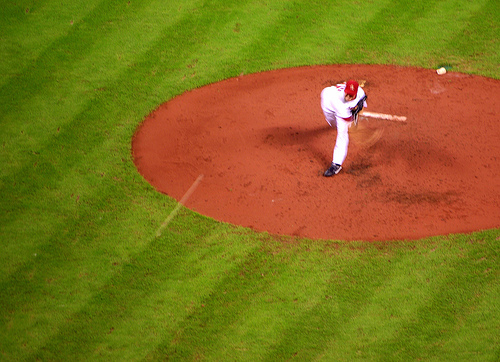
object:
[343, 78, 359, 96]
hat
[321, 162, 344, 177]
shoe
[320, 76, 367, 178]
person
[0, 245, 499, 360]
grass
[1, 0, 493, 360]
ground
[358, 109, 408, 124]
bat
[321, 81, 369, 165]
clothing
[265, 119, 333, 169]
shadow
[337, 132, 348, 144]
knee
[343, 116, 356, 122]
elbow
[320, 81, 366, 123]
shirt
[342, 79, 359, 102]
head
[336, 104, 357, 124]
arm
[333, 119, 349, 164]
leg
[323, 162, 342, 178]
foot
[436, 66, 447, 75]
ball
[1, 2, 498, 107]
air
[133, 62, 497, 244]
mound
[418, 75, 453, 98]
markings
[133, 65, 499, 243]
dirt